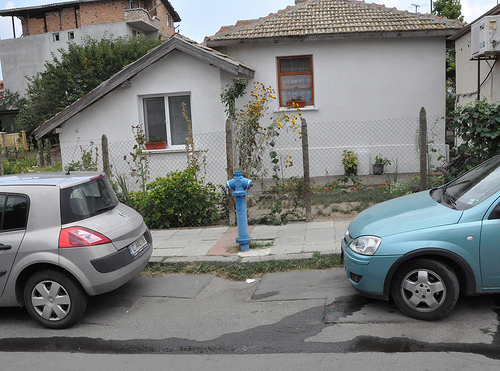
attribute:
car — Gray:
[1, 169, 150, 321]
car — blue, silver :
[2, 168, 155, 333]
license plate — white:
[123, 228, 153, 260]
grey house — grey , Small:
[34, 0, 469, 201]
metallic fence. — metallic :
[49, 121, 496, 212]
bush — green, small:
[130, 168, 226, 225]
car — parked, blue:
[269, 153, 480, 283]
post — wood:
[418, 105, 430, 195]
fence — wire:
[219, 100, 399, 220]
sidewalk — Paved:
[145, 212, 365, 267]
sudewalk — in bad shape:
[171, 230, 266, 257]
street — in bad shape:
[172, 295, 281, 349]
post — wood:
[291, 113, 325, 219]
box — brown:
[141, 139, 170, 156]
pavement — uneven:
[121, 276, 335, 368]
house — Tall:
[1, 0, 182, 40]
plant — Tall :
[214, 72, 304, 177]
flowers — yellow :
[242, 79, 304, 141]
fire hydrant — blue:
[227, 169, 256, 250]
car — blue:
[338, 151, 498, 320]